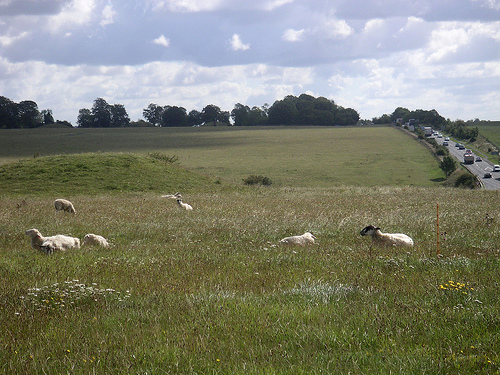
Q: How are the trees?
A: Leafy.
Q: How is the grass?
A: Tall.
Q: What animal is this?
A: Sheep.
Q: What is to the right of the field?
A: Road.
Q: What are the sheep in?
A: Grass field.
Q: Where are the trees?
A: Background.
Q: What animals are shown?
A: Sheep.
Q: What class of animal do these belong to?
A: Mammal.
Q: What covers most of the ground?
A: Grass.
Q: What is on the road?
A: Cars.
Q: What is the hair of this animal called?
A: Wool.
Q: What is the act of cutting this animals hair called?
A: Shearing.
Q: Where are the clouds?
A: In the sky.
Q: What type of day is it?
A: Partly cloudy.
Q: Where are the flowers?
A: In the field.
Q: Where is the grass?
A: In the field.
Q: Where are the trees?
A: Background.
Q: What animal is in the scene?
A: Sheep.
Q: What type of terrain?
A: Hilly.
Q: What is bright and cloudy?
A: Sky.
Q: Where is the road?
A: On the right.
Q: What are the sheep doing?
A: Walking.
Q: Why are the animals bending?
A: They are eating.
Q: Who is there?
A: No one.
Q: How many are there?
A: 7.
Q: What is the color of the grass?
A: Green.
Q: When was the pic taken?
A: During the day.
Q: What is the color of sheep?
A: White.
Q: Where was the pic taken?
A: In a field.